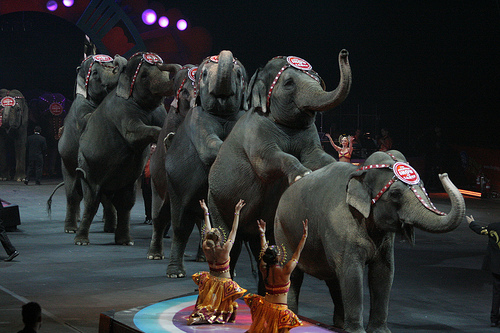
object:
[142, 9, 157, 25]
light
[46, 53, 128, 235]
elephant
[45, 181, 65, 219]
tail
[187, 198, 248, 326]
woman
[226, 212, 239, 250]
arms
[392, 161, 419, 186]
circle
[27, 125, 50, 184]
man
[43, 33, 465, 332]
line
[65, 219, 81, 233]
foot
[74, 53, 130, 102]
head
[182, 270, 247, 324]
costume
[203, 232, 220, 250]
hair